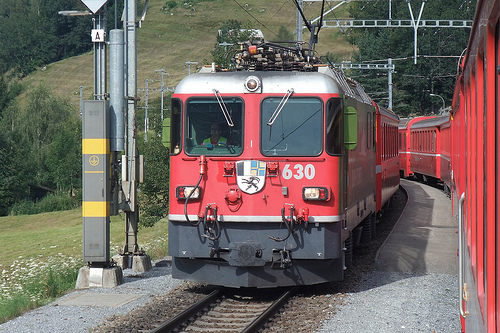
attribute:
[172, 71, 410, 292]
train — red, traveling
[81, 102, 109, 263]
box — gray, yellow, metal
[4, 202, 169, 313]
grass — green, mown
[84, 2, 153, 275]
poles — metal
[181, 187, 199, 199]
headlight — red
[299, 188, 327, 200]
headlight — red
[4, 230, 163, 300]
flowers — white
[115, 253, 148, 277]
base — concrete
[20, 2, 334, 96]
grass — green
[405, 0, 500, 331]
train — traveling, red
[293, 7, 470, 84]
rods — iron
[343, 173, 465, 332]
pavement — gray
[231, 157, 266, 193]
crest — white, blue, yellow, designed, black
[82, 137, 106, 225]
stripes — yellow